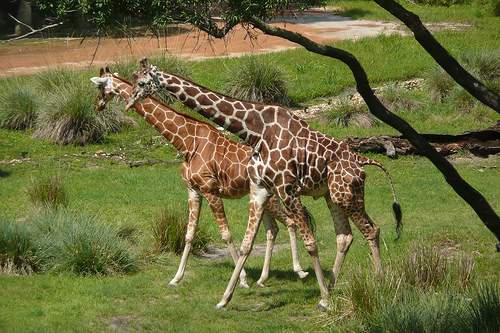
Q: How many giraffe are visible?
A: 2.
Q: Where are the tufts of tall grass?
A: Sporadically on ground.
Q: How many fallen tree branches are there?
A: One.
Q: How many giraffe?
A: Two.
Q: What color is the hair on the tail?
A: Black.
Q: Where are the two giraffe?
A: On the plain.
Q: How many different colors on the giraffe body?
A: Two.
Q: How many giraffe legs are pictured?
A: 8.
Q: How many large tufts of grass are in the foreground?
A: One.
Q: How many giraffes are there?
A: Two.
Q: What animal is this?
A: Giraffes.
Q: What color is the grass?
A: Green.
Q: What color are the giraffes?
A: Brown and white.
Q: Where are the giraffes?
A: In the plains.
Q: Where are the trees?
A: By the animals.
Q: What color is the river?
A: Brown.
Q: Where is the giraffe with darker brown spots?
A: Giraffe closest to camera.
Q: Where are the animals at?
A: Roaming in a grassy area.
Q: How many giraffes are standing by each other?
A: 2.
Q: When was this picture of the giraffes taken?
A: While the sun is up.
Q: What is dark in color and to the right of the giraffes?
A: Tree branches.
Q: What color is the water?
A: Brown.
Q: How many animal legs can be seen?
A: 8.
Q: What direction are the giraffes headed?
A: Left.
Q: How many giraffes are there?
A: 2.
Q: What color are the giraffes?
A: Brown and white.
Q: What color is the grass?
A: Green.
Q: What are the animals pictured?
A: Giraffes.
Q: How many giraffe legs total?
A: 8.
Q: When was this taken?
A: Daytime.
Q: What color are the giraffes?
A: Brown and white.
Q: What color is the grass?
A: Green.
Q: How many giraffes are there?
A: 2.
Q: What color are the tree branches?
A: Brown.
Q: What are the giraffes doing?
A: Walking.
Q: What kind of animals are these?
A: Giraffes.